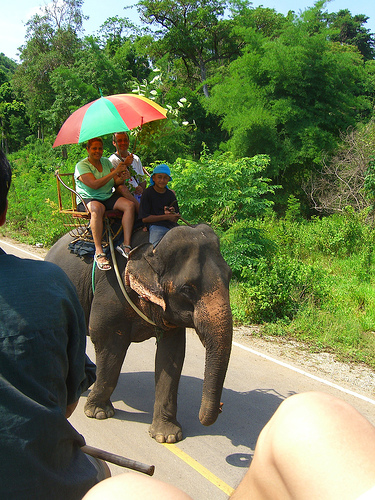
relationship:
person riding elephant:
[76, 134, 140, 274] [30, 211, 237, 450]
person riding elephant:
[107, 129, 149, 211] [30, 211, 237, 450]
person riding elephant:
[141, 163, 186, 251] [30, 211, 237, 450]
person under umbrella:
[76, 134, 140, 274] [41, 90, 179, 148]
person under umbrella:
[107, 129, 149, 211] [41, 90, 179, 148]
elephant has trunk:
[30, 211, 237, 450] [196, 285, 241, 429]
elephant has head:
[30, 211, 237, 450] [124, 218, 242, 435]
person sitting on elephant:
[76, 134, 140, 274] [30, 211, 237, 450]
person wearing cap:
[141, 163, 186, 251] [149, 163, 177, 187]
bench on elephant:
[51, 176, 137, 245] [30, 211, 237, 450]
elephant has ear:
[30, 211, 237, 450] [123, 258, 170, 324]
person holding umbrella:
[76, 134, 140, 274] [41, 90, 179, 148]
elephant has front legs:
[30, 211, 237, 450] [78, 304, 204, 444]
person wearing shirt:
[107, 129, 149, 211] [106, 155, 148, 191]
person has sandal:
[76, 134, 140, 274] [92, 251, 114, 274]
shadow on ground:
[95, 360, 311, 470] [0, 237, 374, 499]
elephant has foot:
[30, 211, 237, 450] [150, 412, 187, 450]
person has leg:
[76, 134, 140, 274] [83, 199, 112, 269]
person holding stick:
[141, 163, 186, 251] [164, 206, 201, 227]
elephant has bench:
[30, 211, 237, 450] [51, 176, 137, 245]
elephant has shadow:
[30, 211, 237, 450] [95, 360, 311, 470]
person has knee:
[76, 134, 140, 274] [84, 201, 111, 219]